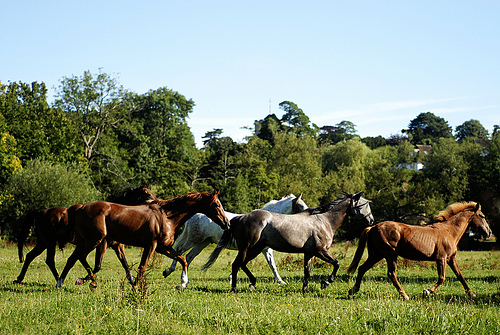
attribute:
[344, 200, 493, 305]
horse — free, walking, brown, running, beautiful, elegant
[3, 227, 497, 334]
field — open, grassy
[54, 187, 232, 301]
horse — running, free, brown, walking, dark brown, beautiful, elegant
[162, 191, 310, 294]
horse — running, walking, free, white, beautiful, elegant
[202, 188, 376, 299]
horse — grey, running, beautiful, free, walking, shiny, elegant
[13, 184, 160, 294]
horse — free, walking, running, brown, beautiful, elegant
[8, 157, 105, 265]
tree — leafy, green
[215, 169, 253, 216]
tree — leafy, green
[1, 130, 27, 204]
tree — leafy, green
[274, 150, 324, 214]
tree — green, leafy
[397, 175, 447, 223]
tree — leafy, green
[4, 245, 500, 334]
grass — green, tall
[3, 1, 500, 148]
sky — clear, cloudy, streaked, blue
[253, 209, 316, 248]
sheen — silvery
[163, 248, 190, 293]
leg — white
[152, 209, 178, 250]
muscles — bulging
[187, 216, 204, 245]
spots — black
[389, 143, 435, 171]
house — white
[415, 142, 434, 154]
roof — red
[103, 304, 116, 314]
flower — yellow, wild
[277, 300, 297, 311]
flower — yellow, wild